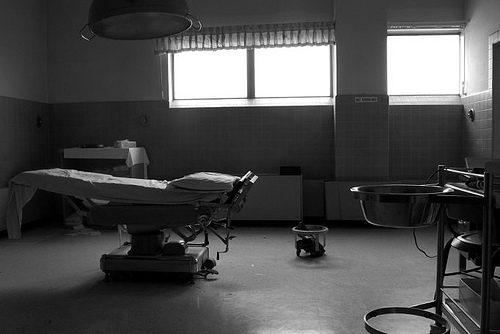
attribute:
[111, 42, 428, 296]
hospital — mental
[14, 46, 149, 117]
room — creepy, hospital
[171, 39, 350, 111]
windows — shining, three, ruffled, square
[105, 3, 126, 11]
light — large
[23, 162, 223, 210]
bed — hospital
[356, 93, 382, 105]
sign — no smoking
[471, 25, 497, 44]
doorway — top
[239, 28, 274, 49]
curtains — small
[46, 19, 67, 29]
wall — part, tile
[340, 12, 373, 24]
tiles — square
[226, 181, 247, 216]
chair — medical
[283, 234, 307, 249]
basin — metal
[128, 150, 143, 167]
cabinet — white